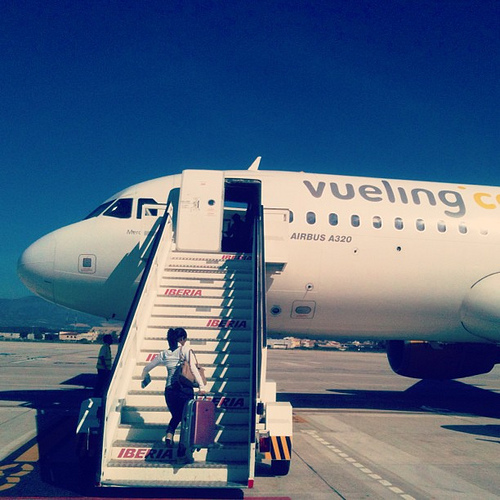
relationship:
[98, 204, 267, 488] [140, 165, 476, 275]
stair at airplane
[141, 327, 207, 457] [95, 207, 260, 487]
passenger on stairs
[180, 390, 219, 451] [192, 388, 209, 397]
luggage in hand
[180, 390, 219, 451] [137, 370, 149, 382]
luggage in hand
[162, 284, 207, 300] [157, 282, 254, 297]
word on stair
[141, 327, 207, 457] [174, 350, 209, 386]
passenger holding bag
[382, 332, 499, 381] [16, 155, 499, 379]
engine on airplane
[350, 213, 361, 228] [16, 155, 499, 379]
window on airplane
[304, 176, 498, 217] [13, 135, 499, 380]
word on plane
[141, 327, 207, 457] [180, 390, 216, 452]
passenger carrying luggage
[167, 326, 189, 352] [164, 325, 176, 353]
hair in ponytail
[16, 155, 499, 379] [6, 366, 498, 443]
airplane casts shadow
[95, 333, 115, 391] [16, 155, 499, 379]
person under airplane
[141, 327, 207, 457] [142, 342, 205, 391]
passenger wearing shirt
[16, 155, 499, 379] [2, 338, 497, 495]
airplane on ground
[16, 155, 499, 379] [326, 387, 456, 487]
airplane on ground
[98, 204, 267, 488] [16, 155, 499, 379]
stair going to airplane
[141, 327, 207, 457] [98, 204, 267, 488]
passenger walking up stair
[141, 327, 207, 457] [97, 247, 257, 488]
passenger walking up stairs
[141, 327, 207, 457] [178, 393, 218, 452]
passenger with suitcase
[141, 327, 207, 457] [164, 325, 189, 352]
passenger with hair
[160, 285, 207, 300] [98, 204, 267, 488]
iberia on stair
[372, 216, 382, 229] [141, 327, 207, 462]
window for passenger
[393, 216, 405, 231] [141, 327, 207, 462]
window for passenger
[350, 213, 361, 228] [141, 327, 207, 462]
window for passenger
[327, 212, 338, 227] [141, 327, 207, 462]
window for passenger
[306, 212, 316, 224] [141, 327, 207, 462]
window for passenger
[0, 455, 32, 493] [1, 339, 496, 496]
number on cement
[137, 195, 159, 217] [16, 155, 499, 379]
window of airplane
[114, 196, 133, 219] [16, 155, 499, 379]
window of airplane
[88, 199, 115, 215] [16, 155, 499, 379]
window of airplane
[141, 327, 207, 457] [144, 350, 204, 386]
passenger wearing white shirt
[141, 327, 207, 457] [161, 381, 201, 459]
passenger wearing dark pants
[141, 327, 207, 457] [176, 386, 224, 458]
passenger carrying suitcase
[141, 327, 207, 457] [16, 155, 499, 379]
passenger walking up stairs on to airplane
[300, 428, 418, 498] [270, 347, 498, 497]
line marking ground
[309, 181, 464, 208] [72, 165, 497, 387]
writing on side of plane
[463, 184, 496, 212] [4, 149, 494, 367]
writing on side of plane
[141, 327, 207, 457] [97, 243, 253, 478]
passenger walking up steps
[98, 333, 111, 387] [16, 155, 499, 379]
person walking under airplane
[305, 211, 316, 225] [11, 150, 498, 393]
window along side of plane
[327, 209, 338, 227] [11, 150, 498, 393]
window along side of plane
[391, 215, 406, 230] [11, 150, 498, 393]
window along side of plane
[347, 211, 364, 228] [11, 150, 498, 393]
window along side of plane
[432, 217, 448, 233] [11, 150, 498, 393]
window along side of plane